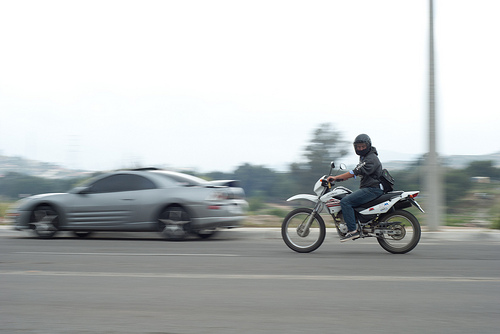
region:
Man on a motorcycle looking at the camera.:
[271, 123, 426, 261]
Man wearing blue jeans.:
[335, 178, 385, 237]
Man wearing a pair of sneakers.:
[339, 222, 361, 244]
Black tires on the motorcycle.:
[276, 202, 325, 258]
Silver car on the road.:
[4, 157, 255, 250]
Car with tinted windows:
[73, 170, 162, 197]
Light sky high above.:
[30, 25, 230, 113]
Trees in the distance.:
[223, 118, 344, 185]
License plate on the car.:
[213, 200, 254, 221]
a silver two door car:
[10, 165, 253, 244]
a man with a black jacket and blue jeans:
[276, 121, 441, 256]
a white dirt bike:
[269, 109, 436, 265]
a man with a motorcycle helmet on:
[327, 138, 392, 245]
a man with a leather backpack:
[341, 131, 403, 253]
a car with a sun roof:
[3, 162, 250, 242]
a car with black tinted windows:
[0, 163, 262, 243]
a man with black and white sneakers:
[342, 123, 394, 243]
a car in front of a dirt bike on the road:
[5, 164, 428, 254]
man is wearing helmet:
[348, 126, 370, 158]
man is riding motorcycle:
[288, 154, 419, 253]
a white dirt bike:
[295, 169, 400, 242]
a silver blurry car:
[20, 123, 234, 260]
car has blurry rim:
[148, 202, 203, 246]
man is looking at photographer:
[338, 134, 370, 166]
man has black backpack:
[372, 158, 417, 209]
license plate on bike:
[405, 181, 424, 213]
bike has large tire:
[278, 193, 330, 273]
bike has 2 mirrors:
[318, 145, 350, 190]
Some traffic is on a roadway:
[10, 63, 497, 315]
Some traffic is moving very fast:
[1, 101, 482, 306]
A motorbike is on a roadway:
[265, 103, 481, 298]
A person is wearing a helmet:
[267, 115, 480, 313]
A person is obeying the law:
[261, 103, 487, 299]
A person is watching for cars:
[262, 108, 458, 290]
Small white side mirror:
[67, 181, 96, 200]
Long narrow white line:
[216, 260, 396, 290]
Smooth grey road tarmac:
[244, 293, 416, 323]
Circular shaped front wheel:
[279, 206, 329, 254]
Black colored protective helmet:
[349, 129, 376, 156]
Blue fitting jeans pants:
[337, 192, 362, 228]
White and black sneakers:
[340, 228, 367, 243]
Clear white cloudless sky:
[299, 70, 404, 105]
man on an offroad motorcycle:
[268, 139, 438, 258]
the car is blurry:
[32, 129, 234, 281]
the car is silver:
[47, 150, 227, 230]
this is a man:
[299, 115, 408, 247]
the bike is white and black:
[265, 155, 421, 257]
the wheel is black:
[276, 193, 338, 245]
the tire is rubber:
[247, 184, 320, 256]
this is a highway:
[54, 239, 374, 314]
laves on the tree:
[302, 129, 321, 143]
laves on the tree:
[293, 161, 315, 175]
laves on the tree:
[265, 182, 286, 207]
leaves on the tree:
[217, 155, 244, 182]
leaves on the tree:
[402, 160, 417, 175]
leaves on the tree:
[258, 167, 279, 188]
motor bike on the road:
[265, 128, 428, 255]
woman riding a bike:
[272, 105, 429, 270]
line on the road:
[16, 251, 493, 294]